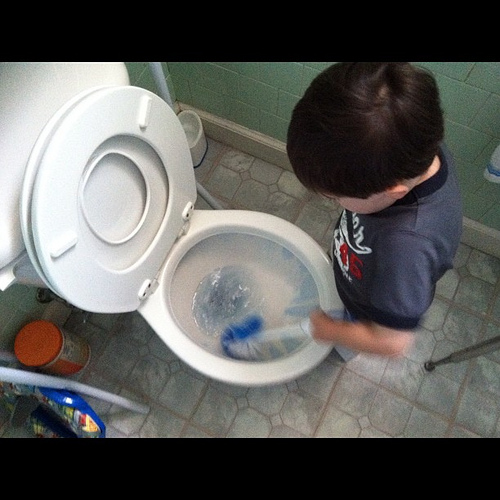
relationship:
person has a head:
[281, 60, 460, 368] [286, 61, 444, 216]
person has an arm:
[281, 60, 460, 368] [311, 305, 413, 356]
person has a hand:
[281, 60, 460, 368] [310, 307, 331, 343]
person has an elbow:
[281, 60, 460, 368] [363, 325, 410, 357]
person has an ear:
[281, 60, 460, 368] [388, 185, 407, 199]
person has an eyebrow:
[281, 60, 460, 368] [322, 194, 337, 202]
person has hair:
[281, 60, 460, 368] [288, 61, 444, 193]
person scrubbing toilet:
[281, 60, 460, 368] [0, 61, 346, 388]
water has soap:
[194, 263, 265, 338] [211, 270, 249, 311]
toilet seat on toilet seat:
[30, 85, 197, 313] [30, 85, 197, 313]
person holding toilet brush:
[281, 60, 460, 368] [222, 309, 345, 360]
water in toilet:
[194, 263, 265, 338] [0, 61, 346, 388]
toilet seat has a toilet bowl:
[30, 85, 197, 313] [172, 235, 319, 361]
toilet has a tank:
[0, 61, 346, 388] [0, 63, 146, 291]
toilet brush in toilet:
[222, 309, 345, 360] [0, 61, 346, 388]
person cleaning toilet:
[281, 60, 460, 368] [0, 61, 346, 388]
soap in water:
[211, 270, 249, 311] [194, 263, 265, 338]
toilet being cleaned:
[0, 61, 346, 388] [222, 309, 345, 360]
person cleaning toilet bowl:
[281, 60, 460, 368] [172, 235, 319, 361]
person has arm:
[281, 60, 460, 368] [311, 305, 413, 356]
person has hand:
[281, 60, 460, 368] [310, 307, 331, 343]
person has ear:
[281, 60, 460, 368] [388, 185, 407, 199]